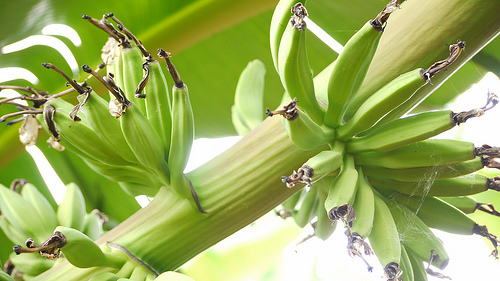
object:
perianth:
[371, 0, 403, 32]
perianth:
[428, 41, 464, 80]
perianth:
[455, 90, 497, 126]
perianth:
[160, 50, 185, 88]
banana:
[322, 1, 401, 125]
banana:
[276, 0, 326, 123]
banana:
[154, 45, 196, 190]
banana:
[78, 64, 167, 174]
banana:
[361, 138, 499, 171]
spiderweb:
[375, 157, 459, 243]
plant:
[5, 1, 498, 275]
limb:
[22, 2, 498, 279]